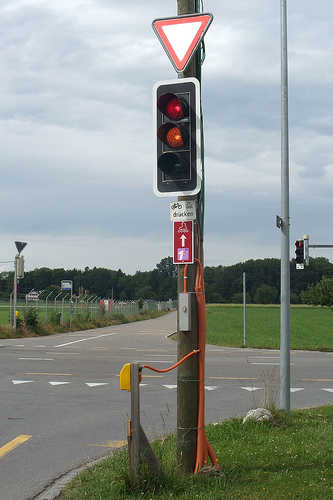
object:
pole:
[174, 1, 203, 470]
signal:
[156, 92, 186, 177]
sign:
[150, 12, 213, 76]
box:
[179, 292, 191, 332]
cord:
[139, 223, 219, 471]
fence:
[0, 288, 176, 327]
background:
[0, 256, 332, 350]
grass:
[56, 403, 332, 498]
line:
[0, 434, 34, 461]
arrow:
[12, 380, 34, 385]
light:
[157, 92, 189, 121]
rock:
[242, 408, 273, 423]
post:
[175, 1, 206, 473]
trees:
[0, 255, 331, 313]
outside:
[1, 1, 328, 498]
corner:
[74, 401, 333, 500]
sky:
[2, 1, 331, 275]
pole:
[279, 0, 289, 415]